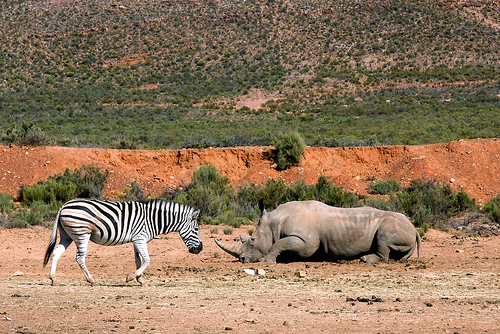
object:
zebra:
[40, 197, 204, 288]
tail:
[40, 209, 60, 267]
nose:
[189, 241, 204, 250]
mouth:
[183, 243, 204, 255]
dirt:
[0, 136, 499, 333]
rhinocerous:
[213, 198, 423, 265]